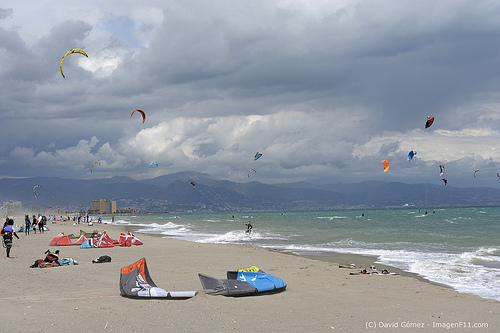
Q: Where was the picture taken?
A: It was taken at the beach.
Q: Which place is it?
A: It is a beach.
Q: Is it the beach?
A: Yes, it is the beach.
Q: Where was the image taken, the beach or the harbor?
A: It was taken at the beach.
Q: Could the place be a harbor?
A: No, it is a beach.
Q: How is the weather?
A: It is cloudy.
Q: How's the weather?
A: It is cloudy.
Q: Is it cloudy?
A: Yes, it is cloudy.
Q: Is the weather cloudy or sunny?
A: It is cloudy.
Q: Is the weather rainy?
A: No, it is cloudy.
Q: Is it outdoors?
A: Yes, it is outdoors.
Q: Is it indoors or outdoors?
A: It is outdoors.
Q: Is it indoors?
A: No, it is outdoors.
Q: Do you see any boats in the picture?
A: No, there are no boats.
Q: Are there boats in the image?
A: No, there are no boats.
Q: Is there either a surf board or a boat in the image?
A: No, there are no boats or surfboards.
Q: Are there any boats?
A: No, there are no boats.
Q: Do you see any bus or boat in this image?
A: No, there are no boats or buses.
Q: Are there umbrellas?
A: No, there are no umbrellas.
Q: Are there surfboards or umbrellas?
A: No, there are no umbrellas or surfboards.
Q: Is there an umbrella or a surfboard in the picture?
A: No, there are no umbrellas or surfboards.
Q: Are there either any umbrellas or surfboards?
A: No, there are no umbrellas or surfboards.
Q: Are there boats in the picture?
A: No, there are no boats.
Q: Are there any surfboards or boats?
A: No, there are no boats or surfboards.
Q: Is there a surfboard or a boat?
A: No, there are no boats or surfboards.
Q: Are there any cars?
A: No, there are no cars.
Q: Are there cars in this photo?
A: No, there are no cars.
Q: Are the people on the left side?
A: Yes, the people are on the left of the image.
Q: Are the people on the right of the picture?
A: No, the people are on the left of the image.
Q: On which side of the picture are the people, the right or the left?
A: The people are on the left of the image.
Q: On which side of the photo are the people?
A: The people are on the left of the image.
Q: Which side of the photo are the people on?
A: The people are on the left of the image.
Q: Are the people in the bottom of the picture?
A: Yes, the people are in the bottom of the image.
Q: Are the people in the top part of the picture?
A: No, the people are in the bottom of the image.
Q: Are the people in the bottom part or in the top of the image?
A: The people are in the bottom of the image.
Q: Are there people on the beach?
A: Yes, there are people on the beach.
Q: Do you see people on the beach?
A: Yes, there are people on the beach.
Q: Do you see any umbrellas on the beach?
A: No, there are people on the beach.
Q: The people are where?
A: The people are in the ocean.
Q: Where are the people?
A: The people are in the ocean.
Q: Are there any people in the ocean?
A: Yes, there are people in the ocean.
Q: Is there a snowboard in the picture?
A: No, there are no snowboards.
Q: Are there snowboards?
A: No, there are no snowboards.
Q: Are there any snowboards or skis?
A: No, there are no snowboards or skis.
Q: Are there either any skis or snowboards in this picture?
A: No, there are no snowboards or skis.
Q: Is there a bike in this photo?
A: No, there are no bikes.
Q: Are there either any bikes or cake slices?
A: No, there are no bikes or cake slices.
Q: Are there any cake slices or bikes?
A: No, there are no bikes or cake slices.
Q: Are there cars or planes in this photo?
A: No, there are no cars or planes.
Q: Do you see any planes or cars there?
A: No, there are no cars or planes.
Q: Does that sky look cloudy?
A: Yes, the sky is cloudy.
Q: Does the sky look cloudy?
A: Yes, the sky is cloudy.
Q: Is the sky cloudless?
A: No, the sky is cloudy.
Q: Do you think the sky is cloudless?
A: No, the sky is cloudy.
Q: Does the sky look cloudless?
A: No, the sky is cloudy.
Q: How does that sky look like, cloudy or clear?
A: The sky is cloudy.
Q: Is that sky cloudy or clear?
A: The sky is cloudy.